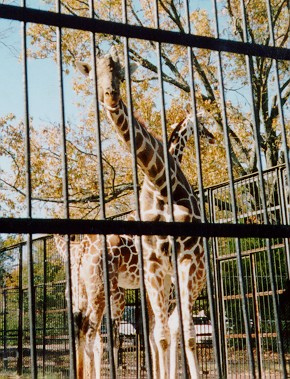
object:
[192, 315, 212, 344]
car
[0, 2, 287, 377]
cage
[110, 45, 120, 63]
ossicone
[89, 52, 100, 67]
ossicone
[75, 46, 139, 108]
giraffe head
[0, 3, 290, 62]
crossbar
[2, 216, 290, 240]
crossbar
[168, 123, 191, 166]
neck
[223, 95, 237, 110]
ground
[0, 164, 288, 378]
fence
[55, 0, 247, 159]
branches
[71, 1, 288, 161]
tree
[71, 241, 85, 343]
giraffe tail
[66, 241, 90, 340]
tail/black fur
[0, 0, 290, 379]
fence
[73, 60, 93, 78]
ears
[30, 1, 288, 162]
tree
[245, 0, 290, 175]
branch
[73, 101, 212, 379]
giraffe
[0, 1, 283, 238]
leafy tree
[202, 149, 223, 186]
leaves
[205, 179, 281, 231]
tree trunk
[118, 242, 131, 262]
spots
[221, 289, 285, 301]
rail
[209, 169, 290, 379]
door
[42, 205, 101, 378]
giraffe tail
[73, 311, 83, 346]
hair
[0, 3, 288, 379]
enclosure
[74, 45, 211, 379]
giraffe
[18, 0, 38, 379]
bars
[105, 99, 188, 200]
neck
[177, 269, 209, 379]
legs